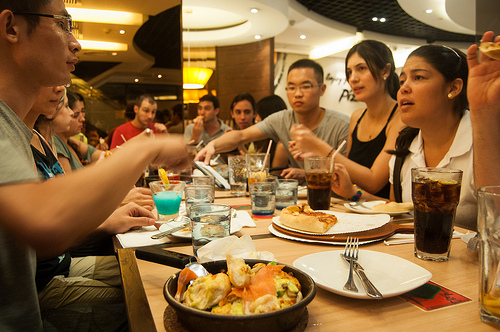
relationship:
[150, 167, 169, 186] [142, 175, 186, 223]
orange on glass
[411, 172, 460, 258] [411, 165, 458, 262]
cola in a glass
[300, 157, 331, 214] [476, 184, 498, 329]
cola in a glass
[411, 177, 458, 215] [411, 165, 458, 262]
ice in a glass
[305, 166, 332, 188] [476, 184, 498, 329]
ice in a glass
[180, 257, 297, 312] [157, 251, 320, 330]
food in bowl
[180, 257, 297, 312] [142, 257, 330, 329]
food in bowl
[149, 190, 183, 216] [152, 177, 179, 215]
liquid in glass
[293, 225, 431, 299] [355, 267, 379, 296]
plate with a knife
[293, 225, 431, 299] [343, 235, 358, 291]
plate with a fork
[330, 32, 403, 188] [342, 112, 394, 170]
woman wearing tank top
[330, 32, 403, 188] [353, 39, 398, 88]
woman has hair